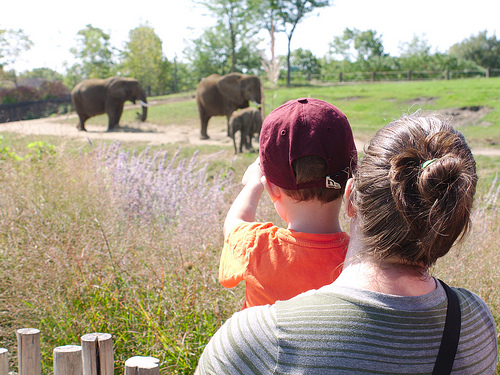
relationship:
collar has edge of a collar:
[270, 223, 335, 252] [249, 211, 299, 262]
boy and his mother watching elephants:
[228, 97, 470, 362] [58, 54, 283, 152]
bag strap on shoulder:
[430, 281, 467, 372] [419, 277, 484, 335]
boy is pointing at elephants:
[226, 136, 298, 266] [62, 68, 275, 163]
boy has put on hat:
[209, 77, 363, 307] [257, 96, 358, 191]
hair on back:
[351, 109, 478, 263] [269, 280, 440, 373]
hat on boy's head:
[251, 90, 365, 194] [259, 84, 358, 208]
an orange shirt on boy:
[215, 228, 353, 309] [209, 77, 363, 307]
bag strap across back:
[430, 278, 464, 375] [256, 273, 473, 371]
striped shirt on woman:
[196, 287, 499, 374] [192, 260, 459, 370]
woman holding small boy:
[191, 112, 498, 372] [214, 83, 359, 302]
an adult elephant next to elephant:
[187, 68, 271, 137] [214, 95, 270, 159]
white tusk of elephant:
[136, 93, 151, 114] [72, 69, 160, 139]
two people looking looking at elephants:
[204, 113, 469, 373] [62, 68, 275, 163]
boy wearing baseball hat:
[216, 97, 357, 311] [246, 95, 364, 194]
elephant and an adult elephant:
[225, 101, 265, 154] [195, 72, 264, 140]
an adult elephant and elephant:
[195, 72, 264, 140] [70, 76, 147, 136]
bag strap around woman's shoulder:
[430, 278, 464, 375] [433, 276, 493, 321]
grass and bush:
[0, 138, 499, 355] [20, 272, 239, 372]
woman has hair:
[191, 112, 498, 372] [355, 116, 478, 266]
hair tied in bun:
[355, 116, 478, 266] [390, 146, 470, 233]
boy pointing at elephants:
[216, 97, 357, 311] [70, 64, 266, 156]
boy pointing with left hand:
[216, 97, 357, 311] [223, 143, 279, 255]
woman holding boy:
[191, 112, 498, 372] [216, 97, 357, 311]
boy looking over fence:
[216, 97, 357, 311] [0, 327, 163, 373]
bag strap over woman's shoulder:
[430, 278, 464, 375] [422, 268, 495, 352]